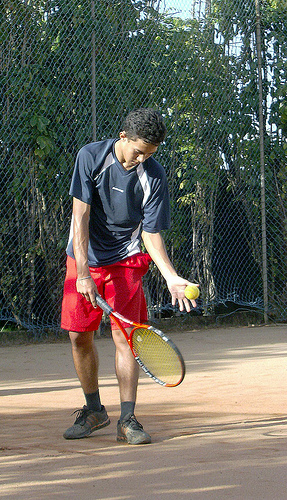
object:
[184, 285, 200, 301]
ball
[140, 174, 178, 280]
arm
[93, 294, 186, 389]
racket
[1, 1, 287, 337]
fence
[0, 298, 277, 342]
opening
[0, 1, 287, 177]
sky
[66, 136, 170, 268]
t-shirt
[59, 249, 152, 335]
shorts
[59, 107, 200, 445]
boy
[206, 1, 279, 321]
tree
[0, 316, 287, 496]
ground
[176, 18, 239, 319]
tree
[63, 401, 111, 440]
shoes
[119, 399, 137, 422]
sock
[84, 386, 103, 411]
sock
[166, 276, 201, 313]
hand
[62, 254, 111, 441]
leg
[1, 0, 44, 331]
trees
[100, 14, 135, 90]
leaves